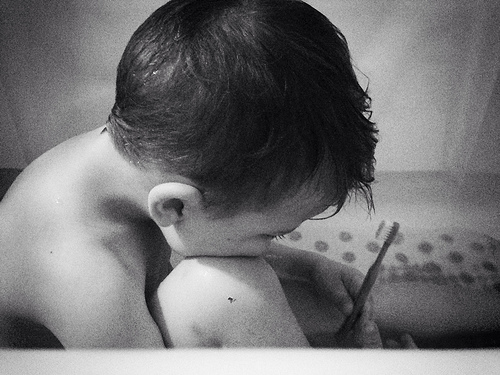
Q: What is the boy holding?
A: Toothbrush.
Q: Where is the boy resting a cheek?
A: Knee.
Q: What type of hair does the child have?
A: Short.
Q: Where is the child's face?
A: On the knee.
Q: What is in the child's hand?
A: Toothbrush.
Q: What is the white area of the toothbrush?
A: Bristles.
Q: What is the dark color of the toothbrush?
A: Handle.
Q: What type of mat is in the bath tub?
A: Polka dots.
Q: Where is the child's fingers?
A: Holding the toothbrush.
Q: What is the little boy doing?
A: Sitting.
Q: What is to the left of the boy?
A: A wall.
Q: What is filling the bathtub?
A: Water.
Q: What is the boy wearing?
A: Nothing.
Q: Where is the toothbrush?
A: In boy's hands.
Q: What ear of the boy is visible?
A: Right.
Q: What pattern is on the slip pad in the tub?
A: Polka dots.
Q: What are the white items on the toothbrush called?
A: Bristles.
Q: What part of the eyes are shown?
A: Eyelashes.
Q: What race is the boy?
A: White.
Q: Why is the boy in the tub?
A: He's taking a bath.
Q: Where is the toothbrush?
A: In the boy's hand.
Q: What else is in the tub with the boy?
A: Water.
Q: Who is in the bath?
A: A young boy.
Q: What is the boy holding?
A: Toothbrush.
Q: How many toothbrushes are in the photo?
A: 1.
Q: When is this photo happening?
A: Bath time.